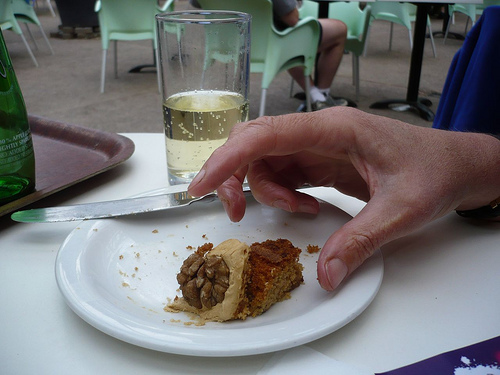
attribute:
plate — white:
[56, 190, 406, 352]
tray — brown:
[3, 104, 143, 224]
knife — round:
[10, 183, 265, 224]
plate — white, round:
[51, 176, 387, 362]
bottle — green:
[0, 26, 37, 205]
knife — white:
[10, 183, 235, 221]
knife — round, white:
[10, 177, 229, 231]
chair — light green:
[201, 3, 327, 120]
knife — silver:
[7, 182, 348, 244]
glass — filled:
[151, 12, 253, 184]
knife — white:
[9, 178, 251, 226]